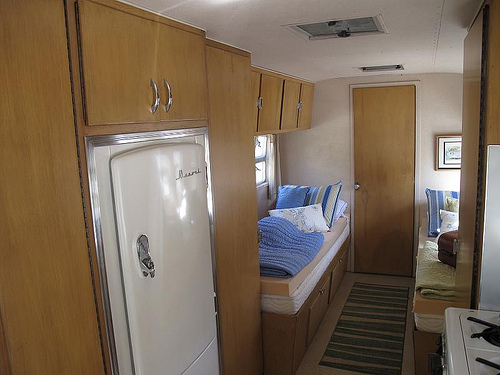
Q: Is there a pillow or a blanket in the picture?
A: Yes, there is a pillow.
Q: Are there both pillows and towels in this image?
A: No, there is a pillow but no towels.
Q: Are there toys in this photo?
A: No, there are no toys.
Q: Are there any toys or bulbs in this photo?
A: No, there are no toys or bulbs.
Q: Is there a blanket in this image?
A: Yes, there is a blanket.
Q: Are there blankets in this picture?
A: Yes, there is a blanket.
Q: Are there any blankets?
A: Yes, there is a blanket.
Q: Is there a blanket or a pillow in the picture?
A: Yes, there is a blanket.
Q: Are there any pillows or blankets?
A: Yes, there is a blanket.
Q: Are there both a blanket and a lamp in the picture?
A: No, there is a blanket but no lamps.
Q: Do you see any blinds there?
A: No, there are no blinds.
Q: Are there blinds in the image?
A: No, there are no blinds.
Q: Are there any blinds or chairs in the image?
A: No, there are no blinds or chairs.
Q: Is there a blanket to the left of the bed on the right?
A: Yes, there is a blanket to the left of the bed.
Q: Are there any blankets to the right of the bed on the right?
A: No, the blanket is to the left of the bed.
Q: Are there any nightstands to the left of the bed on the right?
A: No, there is a blanket to the left of the bed.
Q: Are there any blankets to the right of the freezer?
A: Yes, there is a blanket to the right of the freezer.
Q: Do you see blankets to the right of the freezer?
A: Yes, there is a blanket to the right of the freezer.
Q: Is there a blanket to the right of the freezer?
A: Yes, there is a blanket to the right of the freezer.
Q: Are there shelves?
A: No, there are no shelves.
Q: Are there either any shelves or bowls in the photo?
A: No, there are no shelves or bowls.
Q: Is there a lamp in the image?
A: No, there are no lamps.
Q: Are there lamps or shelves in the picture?
A: No, there are no lamps or shelves.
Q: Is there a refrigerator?
A: Yes, there is a refrigerator.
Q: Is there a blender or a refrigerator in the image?
A: Yes, there is a refrigerator.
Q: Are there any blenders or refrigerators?
A: Yes, there is a refrigerator.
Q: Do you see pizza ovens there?
A: No, there are no pizza ovens.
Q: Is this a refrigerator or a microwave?
A: This is a refrigerator.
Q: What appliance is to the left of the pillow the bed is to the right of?
A: The appliance is a refrigerator.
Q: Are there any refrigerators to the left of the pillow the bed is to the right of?
A: Yes, there is a refrigerator to the left of the pillow.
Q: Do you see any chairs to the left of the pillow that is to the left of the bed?
A: No, there is a refrigerator to the left of the pillow.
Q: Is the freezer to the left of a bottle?
A: No, the freezer is to the left of the pillow.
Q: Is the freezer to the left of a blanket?
A: Yes, the freezer is to the left of a blanket.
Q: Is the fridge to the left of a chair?
A: No, the fridge is to the left of a blanket.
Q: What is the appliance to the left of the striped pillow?
A: The appliance is a refrigerator.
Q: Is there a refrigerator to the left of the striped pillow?
A: Yes, there is a refrigerator to the left of the pillow.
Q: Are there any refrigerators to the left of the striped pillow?
A: Yes, there is a refrigerator to the left of the pillow.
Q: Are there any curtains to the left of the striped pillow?
A: No, there is a refrigerator to the left of the pillow.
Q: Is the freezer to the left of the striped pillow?
A: Yes, the freezer is to the left of the pillow.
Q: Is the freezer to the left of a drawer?
A: No, the freezer is to the left of the pillow.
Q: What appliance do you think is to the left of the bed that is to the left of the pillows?
A: The appliance is a refrigerator.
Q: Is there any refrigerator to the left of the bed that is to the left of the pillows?
A: Yes, there is a refrigerator to the left of the bed.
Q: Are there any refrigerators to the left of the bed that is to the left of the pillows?
A: Yes, there is a refrigerator to the left of the bed.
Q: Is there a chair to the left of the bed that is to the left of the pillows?
A: No, there is a refrigerator to the left of the bed.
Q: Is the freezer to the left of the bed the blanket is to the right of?
A: Yes, the freezer is to the left of the bed.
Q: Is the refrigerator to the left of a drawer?
A: No, the refrigerator is to the left of the bed.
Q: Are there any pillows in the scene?
A: Yes, there is a pillow.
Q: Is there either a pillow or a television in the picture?
A: Yes, there is a pillow.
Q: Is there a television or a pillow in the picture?
A: Yes, there is a pillow.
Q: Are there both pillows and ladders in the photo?
A: No, there is a pillow but no ladders.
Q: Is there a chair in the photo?
A: No, there are no chairs.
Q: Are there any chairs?
A: No, there are no chairs.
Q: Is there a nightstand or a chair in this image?
A: No, there are no chairs or nightstands.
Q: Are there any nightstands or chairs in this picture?
A: No, there are no chairs or nightstands.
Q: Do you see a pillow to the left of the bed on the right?
A: Yes, there is a pillow to the left of the bed.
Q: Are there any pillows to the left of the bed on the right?
A: Yes, there is a pillow to the left of the bed.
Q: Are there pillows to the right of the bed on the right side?
A: No, the pillow is to the left of the bed.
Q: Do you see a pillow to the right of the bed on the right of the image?
A: No, the pillow is to the left of the bed.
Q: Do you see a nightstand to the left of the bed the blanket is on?
A: No, there is a pillow to the left of the bed.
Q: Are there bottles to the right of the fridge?
A: No, there is a pillow to the right of the fridge.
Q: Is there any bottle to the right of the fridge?
A: No, there is a pillow to the right of the fridge.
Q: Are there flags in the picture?
A: No, there are no flags.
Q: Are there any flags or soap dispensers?
A: No, there are no flags or soap dispensers.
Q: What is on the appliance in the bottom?
A: The burner is on the stove.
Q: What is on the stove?
A: The burner is on the stove.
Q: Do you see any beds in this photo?
A: Yes, there is a bed.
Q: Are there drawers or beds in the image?
A: Yes, there is a bed.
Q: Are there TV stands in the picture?
A: No, there are no TV stands.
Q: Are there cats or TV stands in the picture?
A: No, there are no TV stands or cats.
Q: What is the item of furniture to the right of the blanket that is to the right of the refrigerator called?
A: The piece of furniture is a bed.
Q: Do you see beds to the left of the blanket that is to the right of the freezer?
A: No, the bed is to the right of the blanket.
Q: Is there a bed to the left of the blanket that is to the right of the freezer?
A: No, the bed is to the right of the blanket.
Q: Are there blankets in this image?
A: Yes, there is a blanket.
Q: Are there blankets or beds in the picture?
A: Yes, there is a blanket.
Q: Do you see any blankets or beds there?
A: Yes, there is a blanket.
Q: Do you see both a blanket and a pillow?
A: Yes, there are both a blanket and a pillow.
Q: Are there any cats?
A: No, there are no cats.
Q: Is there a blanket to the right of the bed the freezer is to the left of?
A: Yes, there is a blanket to the right of the bed.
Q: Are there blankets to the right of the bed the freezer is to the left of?
A: Yes, there is a blanket to the right of the bed.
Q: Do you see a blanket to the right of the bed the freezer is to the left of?
A: Yes, there is a blanket to the right of the bed.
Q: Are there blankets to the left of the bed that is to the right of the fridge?
A: No, the blanket is to the right of the bed.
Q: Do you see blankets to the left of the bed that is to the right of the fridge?
A: No, the blanket is to the right of the bed.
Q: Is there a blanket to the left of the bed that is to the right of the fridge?
A: No, the blanket is to the right of the bed.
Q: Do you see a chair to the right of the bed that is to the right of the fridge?
A: No, there is a blanket to the right of the bed.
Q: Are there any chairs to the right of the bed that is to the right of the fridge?
A: No, there is a blanket to the right of the bed.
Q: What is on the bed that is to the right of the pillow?
A: The blanket is on the bed.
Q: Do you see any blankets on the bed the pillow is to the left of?
A: Yes, there is a blanket on the bed.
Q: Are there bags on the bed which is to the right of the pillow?
A: No, there is a blanket on the bed.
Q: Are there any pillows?
A: Yes, there are pillows.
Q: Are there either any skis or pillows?
A: Yes, there are pillows.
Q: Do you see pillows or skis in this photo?
A: Yes, there are pillows.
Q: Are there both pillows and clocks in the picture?
A: No, there are pillows but no clocks.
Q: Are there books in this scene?
A: No, there are no books.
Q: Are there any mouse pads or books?
A: No, there are no books or mouse pads.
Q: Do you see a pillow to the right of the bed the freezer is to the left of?
A: Yes, there are pillows to the right of the bed.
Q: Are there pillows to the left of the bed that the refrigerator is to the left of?
A: No, the pillows are to the right of the bed.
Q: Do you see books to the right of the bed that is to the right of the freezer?
A: No, there are pillows to the right of the bed.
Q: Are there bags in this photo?
A: No, there are no bags.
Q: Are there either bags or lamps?
A: No, there are no bags or lamps.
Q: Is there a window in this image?
A: Yes, there is a window.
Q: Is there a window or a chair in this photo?
A: Yes, there is a window.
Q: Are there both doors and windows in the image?
A: Yes, there are both a window and a door.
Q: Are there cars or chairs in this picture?
A: No, there are no cars or chairs.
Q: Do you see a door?
A: Yes, there is a door.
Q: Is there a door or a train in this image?
A: Yes, there is a door.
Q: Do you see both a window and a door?
A: Yes, there are both a door and a window.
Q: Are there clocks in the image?
A: No, there are no clocks.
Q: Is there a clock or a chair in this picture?
A: No, there are no clocks or chairs.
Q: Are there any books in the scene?
A: No, there are no books.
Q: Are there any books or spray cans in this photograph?
A: No, there are no books or spray cans.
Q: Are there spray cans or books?
A: No, there are no books or spray cans.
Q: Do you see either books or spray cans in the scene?
A: No, there are no books or spray cans.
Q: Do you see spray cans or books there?
A: No, there are no books or spray cans.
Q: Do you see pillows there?
A: Yes, there is a pillow.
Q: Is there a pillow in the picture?
A: Yes, there is a pillow.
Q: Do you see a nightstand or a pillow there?
A: Yes, there is a pillow.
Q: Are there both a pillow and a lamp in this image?
A: No, there is a pillow but no lamps.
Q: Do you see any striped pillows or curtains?
A: Yes, there is a striped pillow.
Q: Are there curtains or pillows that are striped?
A: Yes, the pillow is striped.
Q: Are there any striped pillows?
A: Yes, there is a striped pillow.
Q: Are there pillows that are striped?
A: Yes, there is a pillow that is striped.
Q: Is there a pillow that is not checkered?
A: Yes, there is a striped pillow.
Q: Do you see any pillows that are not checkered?
A: Yes, there is a striped pillow.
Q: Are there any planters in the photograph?
A: No, there are no planters.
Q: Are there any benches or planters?
A: No, there are no planters or benches.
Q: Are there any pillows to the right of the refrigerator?
A: Yes, there is a pillow to the right of the refrigerator.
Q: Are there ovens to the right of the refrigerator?
A: No, there is a pillow to the right of the refrigerator.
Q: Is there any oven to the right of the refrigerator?
A: No, there is a pillow to the right of the refrigerator.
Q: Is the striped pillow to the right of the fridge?
A: Yes, the pillow is to the right of the fridge.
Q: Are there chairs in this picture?
A: No, there are no chairs.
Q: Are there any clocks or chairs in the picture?
A: No, there are no chairs or clocks.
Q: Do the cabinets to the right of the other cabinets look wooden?
A: Yes, the cabinets are wooden.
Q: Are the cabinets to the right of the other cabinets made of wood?
A: Yes, the cabinets are made of wood.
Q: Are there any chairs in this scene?
A: No, there are no chairs.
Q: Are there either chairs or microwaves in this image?
A: No, there are no chairs or microwaves.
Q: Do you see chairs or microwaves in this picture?
A: No, there are no chairs or microwaves.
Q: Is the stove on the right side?
A: Yes, the stove is on the right of the image.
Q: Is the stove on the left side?
A: No, the stove is on the right of the image.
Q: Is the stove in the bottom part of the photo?
A: Yes, the stove is in the bottom of the image.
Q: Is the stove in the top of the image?
A: No, the stove is in the bottom of the image.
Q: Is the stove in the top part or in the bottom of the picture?
A: The stove is in the bottom of the image.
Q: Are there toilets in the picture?
A: No, there are no toilets.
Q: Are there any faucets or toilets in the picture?
A: No, there are no toilets or faucets.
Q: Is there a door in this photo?
A: Yes, there is a door.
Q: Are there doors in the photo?
A: Yes, there is a door.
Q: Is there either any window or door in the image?
A: Yes, there is a door.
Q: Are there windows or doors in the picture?
A: Yes, there is a door.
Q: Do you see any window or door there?
A: Yes, there is a door.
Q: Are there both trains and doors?
A: No, there is a door but no trains.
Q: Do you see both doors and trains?
A: No, there is a door but no trains.